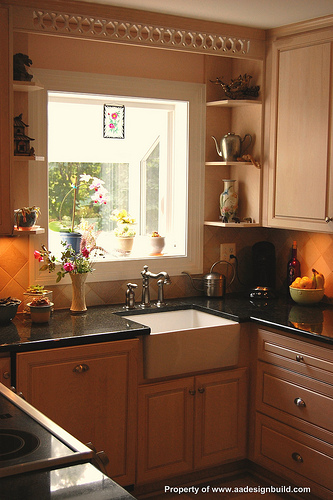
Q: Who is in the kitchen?
A: No one.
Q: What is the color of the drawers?
A: Brown.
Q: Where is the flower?
A: By the sink.